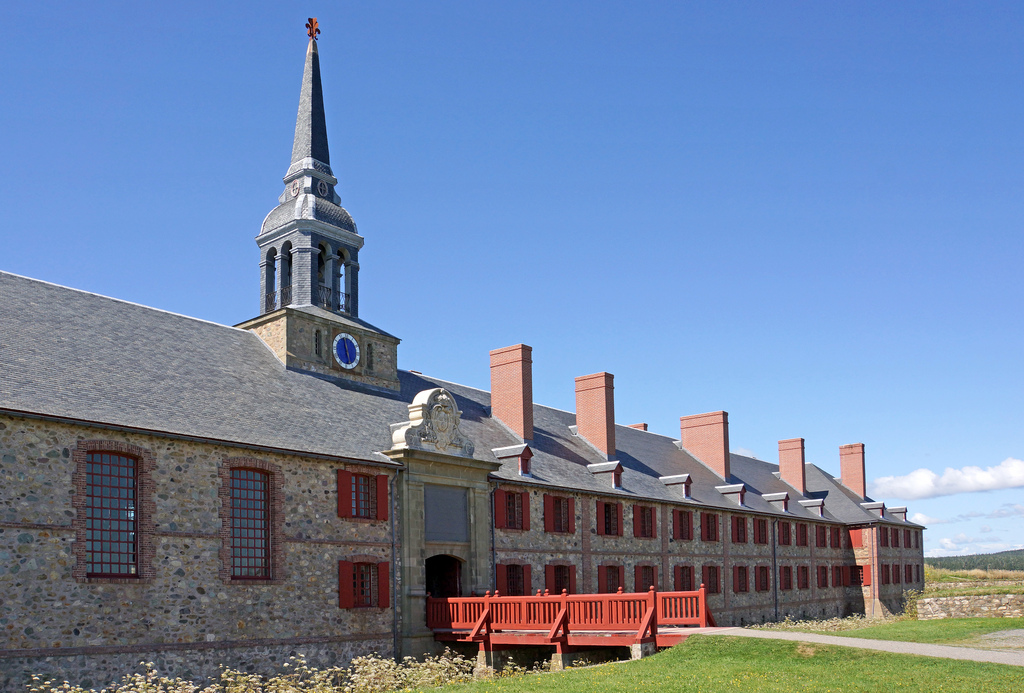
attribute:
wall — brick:
[911, 581, 1022, 625]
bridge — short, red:
[421, 585, 720, 660]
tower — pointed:
[259, 17, 381, 322]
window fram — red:
[330, 449, 393, 523]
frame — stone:
[214, 453, 277, 601]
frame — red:
[326, 550, 396, 613]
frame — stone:
[65, 442, 169, 587]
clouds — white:
[683, 386, 1021, 512]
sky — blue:
[2, 2, 1022, 545]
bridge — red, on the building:
[439, 575, 710, 660]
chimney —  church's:
[487, 348, 535, 442]